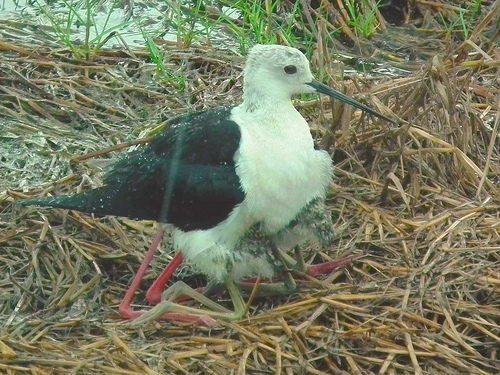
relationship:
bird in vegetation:
[98, 47, 390, 320] [381, 151, 497, 368]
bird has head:
[98, 47, 390, 320] [260, 19, 329, 88]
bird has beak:
[98, 47, 390, 320] [285, 77, 408, 138]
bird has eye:
[98, 47, 390, 320] [278, 51, 296, 87]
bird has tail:
[98, 47, 390, 320] [32, 172, 121, 243]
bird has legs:
[98, 47, 390, 320] [133, 188, 342, 337]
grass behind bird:
[54, 2, 298, 61] [98, 47, 390, 320]